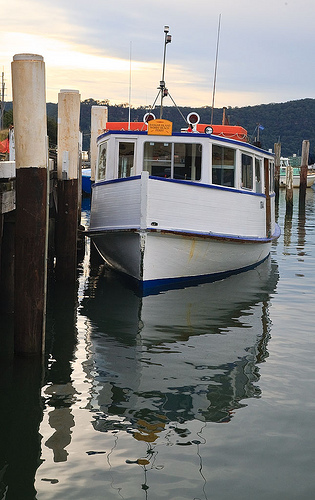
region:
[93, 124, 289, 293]
a white with blue trim colored boat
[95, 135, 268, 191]
a row of windows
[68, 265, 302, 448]
calm waters with a reflection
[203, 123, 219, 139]
a spotlight on the boat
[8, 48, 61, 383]
wood poles that are in the water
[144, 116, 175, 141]
an orange sign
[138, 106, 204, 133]
two of the same shaped items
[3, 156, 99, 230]
a wooden dock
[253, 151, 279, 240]
the door of the boat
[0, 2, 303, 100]
a cloudy sky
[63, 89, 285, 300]
a boat with a cabin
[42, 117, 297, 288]
a blue and white boat with a yellow tag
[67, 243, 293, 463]
a reflection of a boat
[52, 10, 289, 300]
a boat that is docked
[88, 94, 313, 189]
orange objects on top of a boat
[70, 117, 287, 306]
a boat that appears to be wooden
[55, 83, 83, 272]
a sturdy post to support a pier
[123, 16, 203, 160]
a light for night safety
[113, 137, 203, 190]
three front windows of the boat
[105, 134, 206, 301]
the bow of a boat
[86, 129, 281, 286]
white and blue boat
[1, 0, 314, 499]
white and blue boat sitting on the water with its reflection on the surface in the sunset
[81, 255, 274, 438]
reflection of the boat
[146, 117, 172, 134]
orange sign on top of the boat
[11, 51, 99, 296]
pillars to the dock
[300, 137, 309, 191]
pillar to the dock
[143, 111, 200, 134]
two round horns on top of the boat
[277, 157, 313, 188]
white boat in the background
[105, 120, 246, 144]
orange life rafts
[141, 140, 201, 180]
boat has big windows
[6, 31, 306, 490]
the boat is in the photo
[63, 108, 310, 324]
the boat is in the water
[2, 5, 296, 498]
the photo was taken outside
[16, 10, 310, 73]
the sky is clear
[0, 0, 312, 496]
nobody is in the photo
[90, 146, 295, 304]
the boat is blue and white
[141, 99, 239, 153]
the lights are off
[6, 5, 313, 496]
the weather is clear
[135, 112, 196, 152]
the boat has a sign post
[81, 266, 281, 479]
boat's reflection in the water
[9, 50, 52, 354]
cream and brown dock post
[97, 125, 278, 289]
blue and white boat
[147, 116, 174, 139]
orange sign with black letters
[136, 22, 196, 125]
lights on top of boat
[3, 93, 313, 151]
tree covered hill in background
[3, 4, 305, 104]
dimly lit sky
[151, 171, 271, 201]
blue stripe on white boat railing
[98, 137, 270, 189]
white framed boat windows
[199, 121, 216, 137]
small round boat light